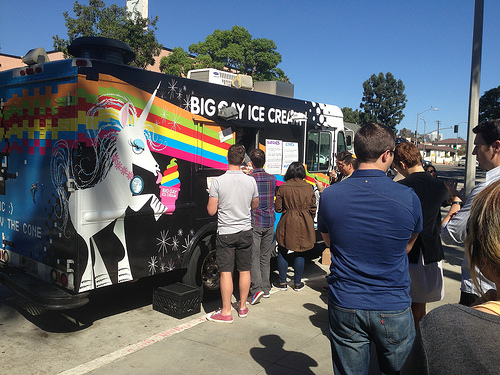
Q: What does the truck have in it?
A: Ice cream.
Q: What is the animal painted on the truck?
A: Unicorn.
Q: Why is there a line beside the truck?
A: Getting ice cream.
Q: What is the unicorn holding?
A: Ice cream cone.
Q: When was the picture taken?
A: Day time.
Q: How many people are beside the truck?
A: Three.